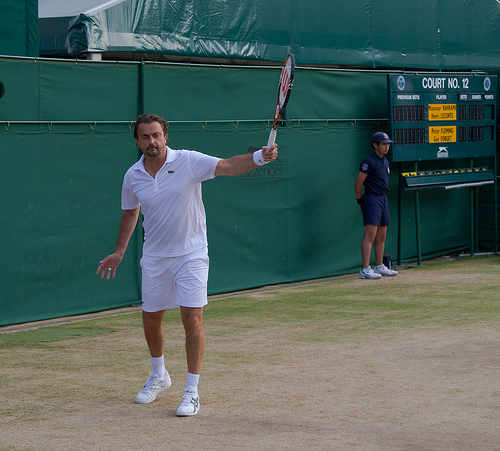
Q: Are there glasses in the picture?
A: No, there are no glasses.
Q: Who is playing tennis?
A: The man is playing tennis.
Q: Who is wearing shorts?
A: The man is wearing shorts.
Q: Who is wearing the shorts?
A: The man is wearing shorts.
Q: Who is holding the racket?
A: The man is holding the racket.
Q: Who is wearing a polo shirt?
A: The man is wearing a polo shirt.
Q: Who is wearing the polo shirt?
A: The man is wearing a polo shirt.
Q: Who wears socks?
A: The man wears socks.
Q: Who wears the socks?
A: The man wears socks.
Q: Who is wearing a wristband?
A: The man is wearing a wristband.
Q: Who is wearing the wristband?
A: The man is wearing a wristband.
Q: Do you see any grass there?
A: Yes, there is grass.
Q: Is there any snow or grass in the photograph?
A: Yes, there is grass.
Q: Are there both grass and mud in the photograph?
A: No, there is grass but no mud.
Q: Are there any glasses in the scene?
A: No, there are no glasses.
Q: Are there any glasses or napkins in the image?
A: No, there are no glasses or napkins.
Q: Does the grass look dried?
A: Yes, the grass is dried.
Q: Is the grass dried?
A: Yes, the grass is dried.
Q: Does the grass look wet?
A: No, the grass is dried.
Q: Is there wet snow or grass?
A: No, there is grass but it is dried.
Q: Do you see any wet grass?
A: No, there is grass but it is dried.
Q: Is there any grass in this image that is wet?
A: No, there is grass but it is dried.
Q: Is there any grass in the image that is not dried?
A: No, there is grass but it is dried.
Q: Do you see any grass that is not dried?
A: No, there is grass but it is dried.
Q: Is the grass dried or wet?
A: The grass is dried.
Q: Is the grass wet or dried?
A: The grass is dried.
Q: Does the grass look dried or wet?
A: The grass is dried.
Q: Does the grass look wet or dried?
A: The grass is dried.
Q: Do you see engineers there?
A: No, there are no engineers.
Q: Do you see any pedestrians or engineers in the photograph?
A: No, there are no engineers or pedestrians.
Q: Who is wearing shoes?
A: The man is wearing shoes.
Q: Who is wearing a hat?
A: The man is wearing a hat.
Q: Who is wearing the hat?
A: The man is wearing a hat.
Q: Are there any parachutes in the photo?
A: No, there are no parachutes.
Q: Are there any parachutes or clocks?
A: No, there are no parachutes or clocks.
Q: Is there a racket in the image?
A: Yes, there is a racket.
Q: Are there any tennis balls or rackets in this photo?
A: Yes, there is a racket.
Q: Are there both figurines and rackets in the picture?
A: No, there is a racket but no figurines.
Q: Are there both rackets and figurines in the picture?
A: No, there is a racket but no figurines.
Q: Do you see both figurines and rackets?
A: No, there is a racket but no figurines.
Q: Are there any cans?
A: No, there are no cans.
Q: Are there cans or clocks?
A: No, there are no cans or clocks.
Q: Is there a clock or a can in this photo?
A: No, there are no cans or clocks.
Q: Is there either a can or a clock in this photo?
A: No, there are no cans or clocks.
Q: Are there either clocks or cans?
A: No, there are no cans or clocks.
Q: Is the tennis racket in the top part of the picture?
A: Yes, the tennis racket is in the top of the image.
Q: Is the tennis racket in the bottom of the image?
A: No, the tennis racket is in the top of the image.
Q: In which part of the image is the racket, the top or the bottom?
A: The racket is in the top of the image.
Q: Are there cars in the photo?
A: No, there are no cars.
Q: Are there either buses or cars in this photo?
A: No, there are no cars or buses.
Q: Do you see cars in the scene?
A: No, there are no cars.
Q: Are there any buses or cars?
A: No, there are no cars or buses.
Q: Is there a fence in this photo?
A: Yes, there is a fence.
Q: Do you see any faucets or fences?
A: Yes, there is a fence.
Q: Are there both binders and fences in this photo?
A: No, there is a fence but no binders.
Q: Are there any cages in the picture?
A: No, there are no cages.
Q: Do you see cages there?
A: No, there are no cages.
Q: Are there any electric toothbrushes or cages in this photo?
A: No, there are no cages or electric toothbrushes.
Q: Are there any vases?
A: No, there are no vases.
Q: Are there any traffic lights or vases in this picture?
A: No, there are no vases or traffic lights.